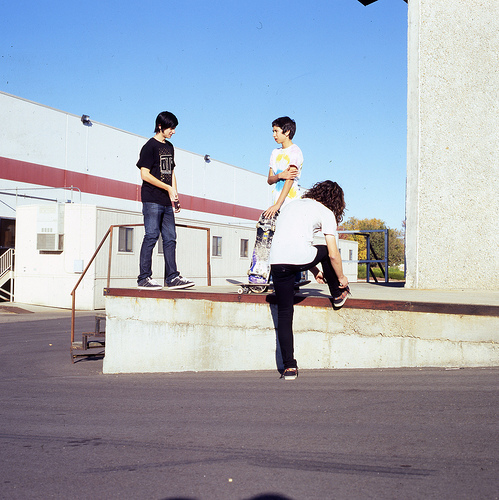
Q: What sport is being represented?
A: Skateboarding.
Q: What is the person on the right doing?
A: Tying shoes.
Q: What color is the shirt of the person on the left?
A: Black.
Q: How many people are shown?
A: Three.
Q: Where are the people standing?
A: Loading dock.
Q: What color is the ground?
A: Gray.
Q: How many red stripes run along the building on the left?
A: One.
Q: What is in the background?
A: Trees.